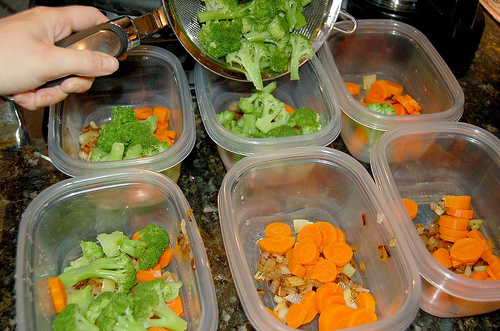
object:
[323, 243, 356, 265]
carrots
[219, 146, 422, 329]
container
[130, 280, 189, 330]
broccoli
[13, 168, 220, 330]
container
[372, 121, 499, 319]
container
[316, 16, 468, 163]
container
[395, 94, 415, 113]
carrots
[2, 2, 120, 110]
woman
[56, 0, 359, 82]
strainer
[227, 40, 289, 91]
broccoli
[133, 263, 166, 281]
carrots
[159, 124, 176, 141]
carrots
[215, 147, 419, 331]
containers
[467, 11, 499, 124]
table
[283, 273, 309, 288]
onions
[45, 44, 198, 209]
container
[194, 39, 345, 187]
container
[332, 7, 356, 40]
loop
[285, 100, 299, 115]
carrots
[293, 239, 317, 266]
carrot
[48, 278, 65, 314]
carrot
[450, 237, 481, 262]
carrot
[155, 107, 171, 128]
carrot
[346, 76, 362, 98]
carrot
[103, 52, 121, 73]
fingernail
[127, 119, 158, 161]
broccoli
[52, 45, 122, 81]
thumb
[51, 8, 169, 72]
handle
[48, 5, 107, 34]
finger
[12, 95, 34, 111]
finger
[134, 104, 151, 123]
carrot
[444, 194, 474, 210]
carrot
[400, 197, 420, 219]
carrot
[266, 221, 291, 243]
carrot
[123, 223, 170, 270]
broccoli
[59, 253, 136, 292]
broccoli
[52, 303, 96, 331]
broccoli